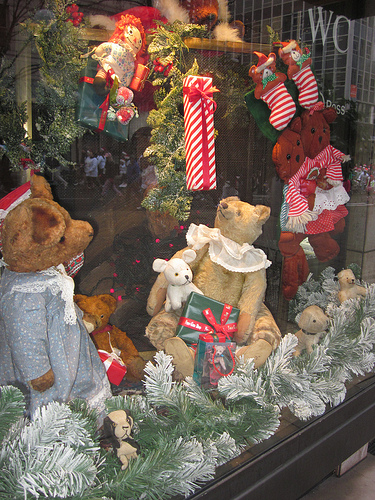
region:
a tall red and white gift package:
[180, 73, 216, 189]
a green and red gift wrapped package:
[175, 293, 237, 342]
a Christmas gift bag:
[196, 332, 237, 386]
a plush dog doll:
[99, 407, 140, 467]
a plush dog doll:
[291, 303, 330, 359]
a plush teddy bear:
[334, 267, 366, 300]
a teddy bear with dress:
[2, 172, 112, 422]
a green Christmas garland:
[142, 21, 213, 218]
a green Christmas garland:
[0, 281, 374, 499]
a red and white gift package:
[96, 347, 128, 386]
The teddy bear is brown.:
[2, 168, 113, 433]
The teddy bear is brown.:
[145, 189, 282, 382]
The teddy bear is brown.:
[72, 288, 146, 382]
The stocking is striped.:
[240, 35, 297, 136]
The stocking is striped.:
[272, 35, 323, 114]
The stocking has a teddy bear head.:
[246, 44, 295, 131]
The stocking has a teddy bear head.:
[271, 33, 327, 113]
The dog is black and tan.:
[92, 403, 153, 476]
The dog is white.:
[146, 240, 207, 315]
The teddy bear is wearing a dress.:
[0, 172, 119, 445]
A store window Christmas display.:
[4, 10, 369, 472]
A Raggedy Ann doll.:
[91, 0, 156, 102]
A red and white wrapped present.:
[174, 62, 228, 198]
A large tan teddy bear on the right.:
[146, 171, 278, 374]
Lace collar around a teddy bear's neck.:
[185, 212, 271, 275]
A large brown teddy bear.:
[2, 176, 122, 434]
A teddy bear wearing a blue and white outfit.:
[2, 175, 124, 415]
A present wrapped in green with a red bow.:
[182, 280, 241, 351]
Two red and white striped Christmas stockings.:
[240, 30, 326, 131]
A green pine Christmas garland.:
[3, 324, 373, 499]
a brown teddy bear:
[70, 293, 147, 385]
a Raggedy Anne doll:
[92, 10, 148, 105]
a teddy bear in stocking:
[249, 50, 297, 130]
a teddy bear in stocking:
[274, 36, 318, 109]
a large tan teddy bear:
[145, 194, 280, 349]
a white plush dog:
[152, 248, 202, 310]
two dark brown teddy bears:
[272, 108, 351, 297]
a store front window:
[0, 1, 373, 498]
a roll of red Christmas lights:
[108, 225, 185, 301]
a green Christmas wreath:
[1, 0, 91, 169]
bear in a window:
[199, 189, 276, 364]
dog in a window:
[300, 297, 332, 353]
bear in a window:
[333, 261, 367, 309]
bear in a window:
[2, 180, 101, 401]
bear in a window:
[242, 50, 295, 128]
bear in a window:
[286, 33, 318, 87]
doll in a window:
[90, 15, 150, 96]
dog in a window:
[105, 397, 143, 468]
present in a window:
[69, 99, 133, 159]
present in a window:
[177, 67, 217, 196]